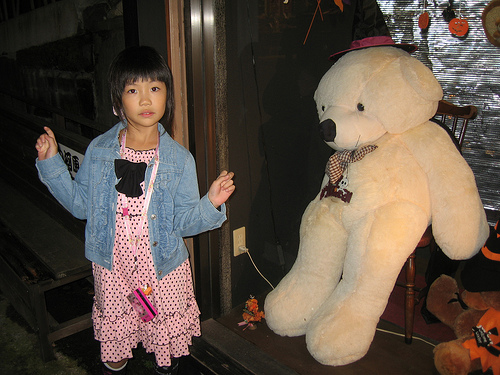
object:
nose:
[317, 117, 337, 143]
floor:
[273, 316, 478, 374]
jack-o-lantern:
[448, 17, 470, 37]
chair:
[382, 232, 435, 345]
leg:
[323, 200, 426, 327]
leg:
[262, 195, 352, 301]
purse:
[126, 288, 158, 323]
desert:
[233, 227, 247, 257]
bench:
[0, 181, 107, 358]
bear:
[266, 35, 490, 366]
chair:
[28, 57, 106, 121]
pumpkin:
[414, 14, 434, 31]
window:
[376, 0, 499, 213]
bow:
[113, 155, 148, 197]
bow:
[324, 142, 377, 185]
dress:
[90, 130, 207, 370]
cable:
[239, 242, 280, 289]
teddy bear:
[427, 222, 497, 375]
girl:
[37, 44, 235, 375]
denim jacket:
[34, 119, 228, 280]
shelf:
[187, 294, 499, 374]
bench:
[191, 315, 293, 375]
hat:
[329, 35, 417, 64]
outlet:
[232, 225, 246, 257]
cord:
[233, 244, 440, 358]